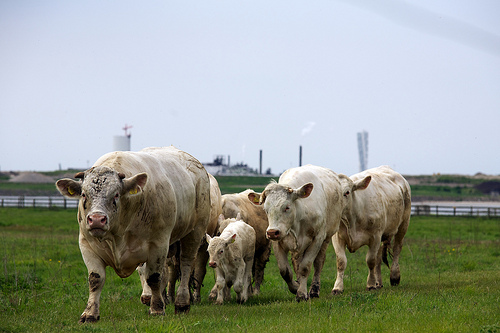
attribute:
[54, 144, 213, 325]
cow — white, furry, first, large, biggest, in front, in line, walking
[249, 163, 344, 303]
cow — large, white, second, in line, walking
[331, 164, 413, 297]
cow — third, large, white, in line, walking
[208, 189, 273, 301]
cow — in line, walking, white, large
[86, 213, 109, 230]
nose — pink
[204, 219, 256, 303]
cow — small, baby, in line, walking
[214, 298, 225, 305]
foot — in front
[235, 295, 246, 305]
foot — in front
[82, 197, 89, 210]
spot — black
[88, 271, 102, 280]
spot — black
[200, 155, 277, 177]
building — in background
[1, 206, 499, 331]
field — green, grassy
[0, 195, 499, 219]
fence — wooden, long, distant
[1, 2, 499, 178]
sky — overcast, light blue, distant, gray, overhead, blue, above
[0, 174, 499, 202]
grass — in background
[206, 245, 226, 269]
face — cute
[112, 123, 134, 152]
silo — distant, white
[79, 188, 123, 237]
face — large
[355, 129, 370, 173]
tower — steel, distance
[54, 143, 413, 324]
herd — small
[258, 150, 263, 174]
smoke stack — tall, distant